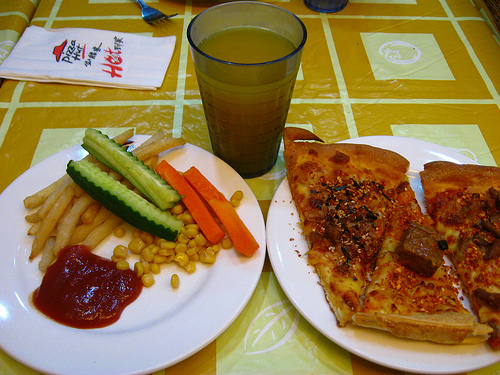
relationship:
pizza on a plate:
[420, 160, 496, 349] [267, 140, 484, 370]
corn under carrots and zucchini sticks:
[114, 206, 220, 278] [70, 125, 185, 235]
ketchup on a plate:
[31, 243, 141, 325] [0, 132, 266, 374]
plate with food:
[102, 289, 219, 375] [13, 120, 259, 287]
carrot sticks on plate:
[206, 258, 234, 336] [170, 223, 260, 375]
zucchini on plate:
[59, 119, 186, 246] [0, 132, 266, 374]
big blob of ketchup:
[40, 268, 124, 346] [31, 243, 141, 325]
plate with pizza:
[110, 312, 324, 375] [292, 119, 476, 371]